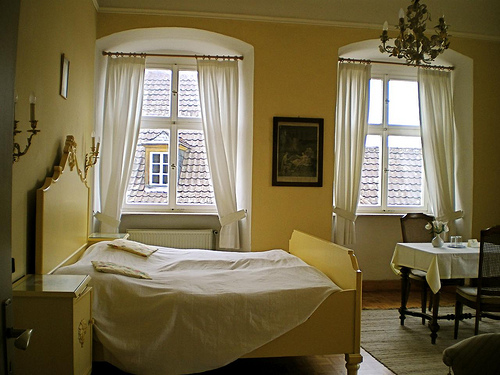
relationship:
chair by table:
[398, 212, 462, 340] [394, 237, 500, 348]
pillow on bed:
[92, 259, 153, 281] [32, 132, 365, 375]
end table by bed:
[5, 272, 94, 375] [32, 132, 365, 375]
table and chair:
[394, 237, 500, 348] [398, 212, 462, 340]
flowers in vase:
[423, 217, 451, 235] [431, 230, 446, 249]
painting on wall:
[269, 114, 326, 188] [98, 8, 499, 289]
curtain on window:
[332, 55, 373, 254] [347, 70, 453, 210]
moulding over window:
[337, 35, 476, 70] [347, 70, 453, 210]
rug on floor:
[356, 305, 498, 373] [93, 289, 499, 373]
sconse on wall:
[9, 91, 44, 170] [10, 0, 98, 373]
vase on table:
[431, 230, 446, 249] [394, 237, 500, 348]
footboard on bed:
[288, 226, 365, 374] [32, 132, 365, 375]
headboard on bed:
[32, 132, 90, 276] [32, 132, 365, 375]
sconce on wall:
[83, 130, 103, 178] [10, 0, 98, 373]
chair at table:
[398, 212, 462, 340] [394, 237, 500, 348]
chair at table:
[451, 222, 499, 340] [394, 237, 500, 348]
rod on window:
[98, 47, 247, 65] [106, 61, 235, 212]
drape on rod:
[98, 50, 147, 234] [98, 47, 247, 65]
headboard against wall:
[32, 132, 90, 276] [10, 0, 98, 373]